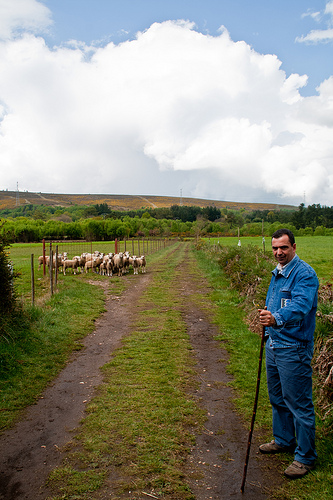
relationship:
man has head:
[258, 226, 320, 478] [269, 228, 297, 263]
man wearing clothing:
[258, 226, 320, 478] [263, 254, 319, 352]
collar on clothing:
[270, 257, 299, 280] [263, 254, 319, 352]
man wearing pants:
[258, 226, 320, 478] [264, 348, 315, 461]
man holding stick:
[258, 226, 320, 478] [239, 304, 268, 491]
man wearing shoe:
[258, 226, 320, 478] [257, 439, 278, 452]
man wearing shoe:
[258, 226, 320, 478] [284, 459, 309, 477]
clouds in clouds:
[1, 2, 332, 205] [0, 1, 332, 211]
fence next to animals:
[2, 234, 175, 309] [38, 250, 148, 276]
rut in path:
[0, 270, 148, 498] [0, 240, 275, 498]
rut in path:
[173, 271, 279, 498] [0, 240, 275, 498]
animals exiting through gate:
[39, 249, 145, 275] [40, 238, 118, 273]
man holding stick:
[258, 226, 320, 478] [241, 299, 279, 438]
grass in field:
[312, 237, 331, 258] [234, 227, 332, 289]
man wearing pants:
[258, 226, 320, 478] [264, 348, 319, 466]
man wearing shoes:
[258, 223, 312, 279] [253, 429, 322, 469]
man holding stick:
[258, 226, 320, 478] [238, 314, 282, 479]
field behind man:
[172, 225, 277, 294] [241, 227, 331, 319]